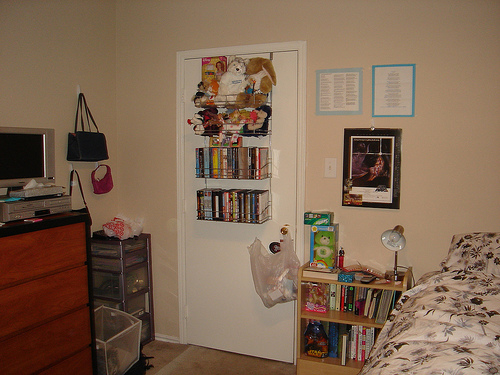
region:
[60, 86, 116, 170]
black purse hanging on the wall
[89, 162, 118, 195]
small red purse hanging on wall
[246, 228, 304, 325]
white plastic bag hanging on door's handle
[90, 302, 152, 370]
white mesh clothes basket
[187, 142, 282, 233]
book shelves on back of white door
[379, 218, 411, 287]
gold lamp laying on book shelf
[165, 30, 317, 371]
solid white door with knob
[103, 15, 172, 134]
solid pink wall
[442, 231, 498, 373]
portion of bed spread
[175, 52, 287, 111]
different color teddy bears hanging on door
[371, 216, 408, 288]
a desk lamp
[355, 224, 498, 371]
a bed with comforter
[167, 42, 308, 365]
a white closed door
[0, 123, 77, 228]
a TV and DVD player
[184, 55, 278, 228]
a wire rack of books and plush toys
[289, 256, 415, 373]
a small two level bookcase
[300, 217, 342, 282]
a vintage green teddy bear in original packaging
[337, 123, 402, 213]
a framed vintage Star Wars: A New Hope poster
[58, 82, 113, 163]
a black purse hanging on the wall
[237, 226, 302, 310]
a plastic disposable grocery bag with trash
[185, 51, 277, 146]
Plush animals on door hanger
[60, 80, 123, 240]
Black and pink hanging purses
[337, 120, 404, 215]
Star Wars poster with black border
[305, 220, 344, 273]
Green Care Bear in box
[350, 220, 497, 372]
Bed with white and black floral sheets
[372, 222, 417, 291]
Small reading lamp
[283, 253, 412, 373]
Small wooden book shelf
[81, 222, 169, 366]
Plastic storage drawers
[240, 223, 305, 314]
White plastic bag on doorknob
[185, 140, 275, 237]
Books on hanging door organizer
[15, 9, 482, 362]
A clean and orderly bedroom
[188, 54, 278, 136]
A rack of stuffed animals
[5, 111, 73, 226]
A computer screen on a stereo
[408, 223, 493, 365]
A bed with flower print sheets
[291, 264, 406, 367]
Small book shelves filled with books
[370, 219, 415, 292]
A brown night stand lamp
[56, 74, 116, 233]
Three purses hanging from a wall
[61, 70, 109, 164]
A black purse on a white hook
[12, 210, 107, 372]
A dresser with four drawers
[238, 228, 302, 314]
Plastic bag hanging from a door knob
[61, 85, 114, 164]
Black purse hanging on wall.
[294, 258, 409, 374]
Books on the bookcase.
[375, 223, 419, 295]
Lamp sitting on bookcase.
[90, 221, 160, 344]
Plastic bin in the corner.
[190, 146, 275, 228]
Books on door rack.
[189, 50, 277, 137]
Toys on door rack.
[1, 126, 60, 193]
Computer sitting on chest.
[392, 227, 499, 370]
Bed spread covered in flowers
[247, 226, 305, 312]
Plastic bag on door knob.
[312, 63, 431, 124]
Blue trimmed paper taped to wall.